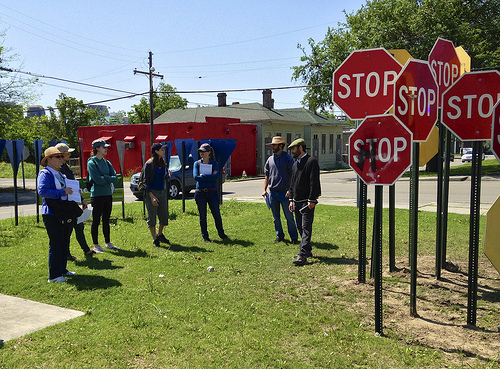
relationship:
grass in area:
[1, 193, 499, 367] [156, 310, 245, 358]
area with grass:
[156, 310, 245, 358] [1, 193, 499, 367]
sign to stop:
[334, 46, 402, 117] [338, 67, 398, 103]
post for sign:
[370, 185, 389, 334] [334, 46, 402, 117]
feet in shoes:
[202, 234, 234, 244] [199, 233, 230, 245]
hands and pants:
[288, 200, 317, 209] [292, 201, 317, 253]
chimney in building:
[260, 89, 277, 109] [163, 106, 342, 173]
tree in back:
[134, 88, 186, 122] [1, 85, 499, 178]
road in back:
[4, 156, 496, 221] [1, 85, 499, 178]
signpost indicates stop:
[395, 59, 439, 314] [397, 83, 435, 118]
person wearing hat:
[287, 135, 325, 266] [288, 137, 303, 151]